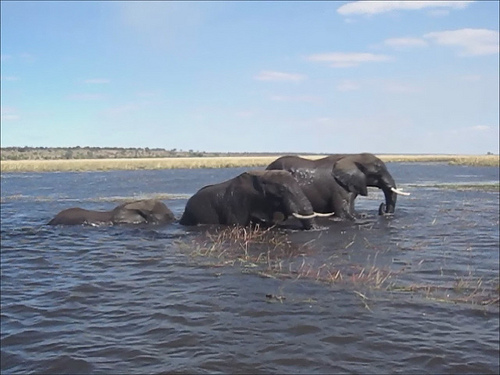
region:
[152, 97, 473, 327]
the elephant is wet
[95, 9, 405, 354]
the elephant is wet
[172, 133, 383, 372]
the elephant is wet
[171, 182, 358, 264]
elephant on the sea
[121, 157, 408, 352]
elephant on the sea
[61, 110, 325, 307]
elephant on the sea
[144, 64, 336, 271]
elephant on the sea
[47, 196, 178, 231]
elephant mostly submerged in water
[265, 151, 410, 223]
elephant knee-high in water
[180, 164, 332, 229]
elephant chest-high in water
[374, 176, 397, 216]
trunk of elephant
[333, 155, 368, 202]
ear of elephant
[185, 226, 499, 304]
reeds growing in water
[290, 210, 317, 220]
left tusk of grey elephant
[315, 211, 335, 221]
right tusk of elephant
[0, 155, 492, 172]
brown vegetation along river bank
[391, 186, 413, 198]
right tusk of elephant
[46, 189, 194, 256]
an elephant in water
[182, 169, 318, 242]
an elephant in water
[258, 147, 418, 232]
an elephant in water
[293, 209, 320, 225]
this is a an elephant tusk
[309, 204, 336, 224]
this is a an elephant tusk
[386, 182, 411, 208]
this is a an elephant tusk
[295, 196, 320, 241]
this is an elephant trunk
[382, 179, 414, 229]
this is an elephant trunk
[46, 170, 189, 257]
the elephant is almost submerged in water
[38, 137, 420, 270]
three elephants in the water